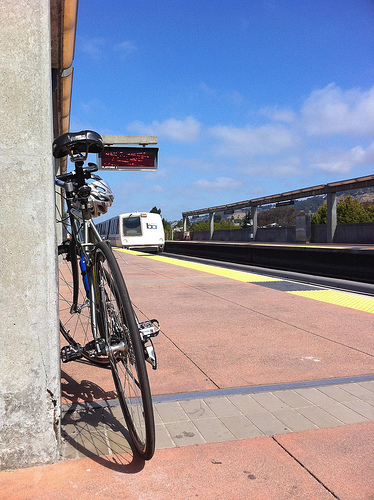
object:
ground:
[0, 244, 374, 500]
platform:
[134, 243, 374, 458]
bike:
[51, 124, 164, 463]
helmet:
[66, 171, 116, 221]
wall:
[0, 0, 60, 470]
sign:
[98, 133, 161, 172]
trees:
[346, 206, 358, 222]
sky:
[67, 0, 374, 228]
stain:
[93, 211, 166, 253]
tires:
[93, 238, 159, 464]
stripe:
[113, 248, 374, 318]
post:
[52, 129, 103, 201]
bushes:
[203, 218, 210, 228]